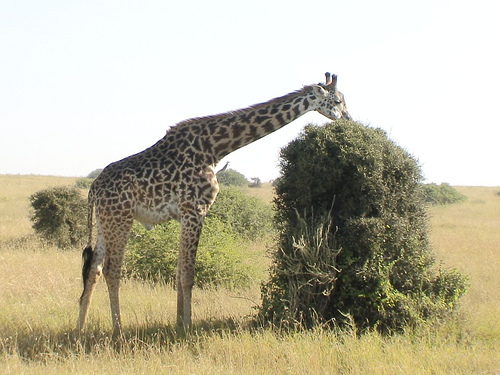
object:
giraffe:
[72, 72, 353, 343]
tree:
[254, 119, 473, 338]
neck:
[211, 87, 313, 161]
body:
[97, 142, 219, 230]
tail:
[78, 189, 99, 304]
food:
[321, 133, 374, 174]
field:
[247, 174, 498, 344]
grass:
[241, 334, 419, 372]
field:
[3, 171, 181, 372]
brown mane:
[166, 84, 314, 133]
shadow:
[7, 318, 210, 345]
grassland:
[0, 196, 500, 374]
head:
[313, 72, 355, 123]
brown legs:
[179, 209, 201, 339]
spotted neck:
[233, 112, 280, 130]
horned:
[332, 73, 338, 88]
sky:
[65, 0, 487, 66]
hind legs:
[102, 185, 137, 342]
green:
[337, 141, 378, 191]